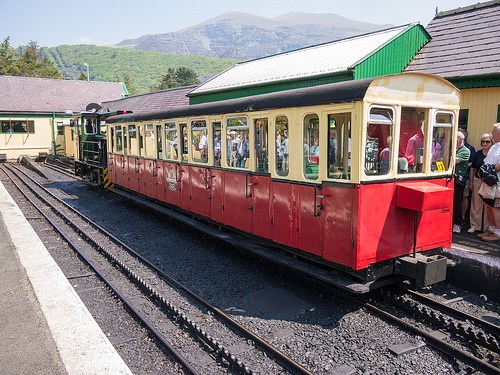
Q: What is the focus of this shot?
A: Train loading at station.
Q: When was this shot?
A: Daytime.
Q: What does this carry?
A: People.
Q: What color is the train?
A: Red, yellow.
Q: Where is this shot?
A: Platform.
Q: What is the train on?
A: Train tracks.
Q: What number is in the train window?
A: 12.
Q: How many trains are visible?
A: 1.